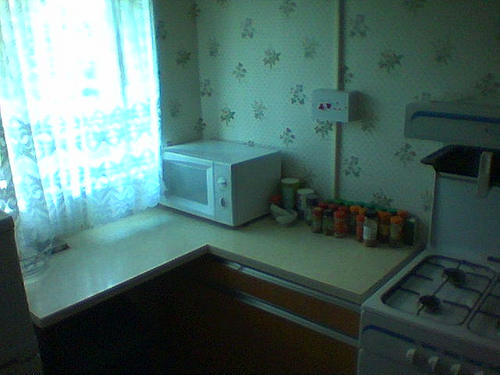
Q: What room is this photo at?
A: It is at the kitchen.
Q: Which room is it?
A: It is a kitchen.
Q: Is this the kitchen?
A: Yes, it is the kitchen.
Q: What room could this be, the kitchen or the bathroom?
A: It is the kitchen.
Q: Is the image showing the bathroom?
A: No, the picture is showing the kitchen.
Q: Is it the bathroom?
A: No, it is the kitchen.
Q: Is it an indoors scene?
A: Yes, it is indoors.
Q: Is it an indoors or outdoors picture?
A: It is indoors.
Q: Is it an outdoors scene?
A: No, it is indoors.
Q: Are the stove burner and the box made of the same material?
A: Yes, both the stove burner and the box are made of metal.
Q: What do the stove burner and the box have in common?
A: The material, both the stove burner and the box are metallic.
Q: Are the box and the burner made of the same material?
A: Yes, both the box and the burner are made of metal.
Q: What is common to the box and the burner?
A: The material, both the box and the burner are metallic.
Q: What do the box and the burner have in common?
A: The material, both the box and the burner are metallic.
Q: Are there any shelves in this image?
A: No, there are no shelves.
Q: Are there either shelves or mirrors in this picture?
A: No, there are no shelves or mirrors.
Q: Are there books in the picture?
A: No, there are no books.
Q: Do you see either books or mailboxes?
A: No, there are no books or mailboxes.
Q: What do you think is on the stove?
A: The stove burner is on the stove.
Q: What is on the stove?
A: The stove burner is on the stove.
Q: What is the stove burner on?
A: The stove burner is on the stove.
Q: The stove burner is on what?
A: The stove burner is on the stove.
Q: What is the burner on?
A: The stove burner is on the stove.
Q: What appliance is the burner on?
A: The burner is on the stove.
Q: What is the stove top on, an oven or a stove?
A: The stove top is on a stove.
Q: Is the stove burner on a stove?
A: Yes, the stove burner is on a stove.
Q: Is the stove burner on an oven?
A: No, the stove burner is on a stove.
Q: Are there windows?
A: Yes, there is a window.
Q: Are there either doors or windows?
A: Yes, there is a window.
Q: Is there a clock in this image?
A: No, there are no clocks.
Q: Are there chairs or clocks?
A: No, there are no clocks or chairs.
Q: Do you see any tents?
A: No, there are no tents.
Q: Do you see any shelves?
A: No, there are no shelves.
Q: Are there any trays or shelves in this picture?
A: No, there are no shelves or trays.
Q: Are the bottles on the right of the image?
A: Yes, the bottles are on the right of the image.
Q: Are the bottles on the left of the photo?
A: No, the bottles are on the right of the image.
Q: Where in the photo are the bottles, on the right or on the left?
A: The bottles are on the right of the image.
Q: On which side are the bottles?
A: The bottles are on the right of the image.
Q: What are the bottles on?
A: The bottles are on the counter top.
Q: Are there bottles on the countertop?
A: Yes, there are bottles on the countertop.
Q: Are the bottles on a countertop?
A: Yes, the bottles are on a countertop.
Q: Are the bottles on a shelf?
A: No, the bottles are on a countertop.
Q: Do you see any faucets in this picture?
A: No, there are no faucets.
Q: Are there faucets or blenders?
A: No, there are no faucets or blenders.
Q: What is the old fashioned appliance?
A: The appliance is a stove.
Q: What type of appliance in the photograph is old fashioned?
A: The appliance is a stove.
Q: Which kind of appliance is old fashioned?
A: The appliance is a stove.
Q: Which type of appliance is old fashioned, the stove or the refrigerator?
A: The stove is old fashioned.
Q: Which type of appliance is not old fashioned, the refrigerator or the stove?
A: The refrigerator is not old fashioned.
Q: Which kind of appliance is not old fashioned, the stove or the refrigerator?
A: The refrigerator is not old fashioned.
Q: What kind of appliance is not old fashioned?
A: The appliance is a refrigerator.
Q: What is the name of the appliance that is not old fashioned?
A: The appliance is a refrigerator.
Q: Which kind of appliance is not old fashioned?
A: The appliance is a refrigerator.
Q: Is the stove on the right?
A: Yes, the stove is on the right of the image.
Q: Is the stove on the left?
A: No, the stove is on the right of the image.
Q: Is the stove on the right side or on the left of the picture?
A: The stove is on the right of the image.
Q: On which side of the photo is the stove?
A: The stove is on the right of the image.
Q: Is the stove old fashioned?
A: Yes, the stove is old fashioned.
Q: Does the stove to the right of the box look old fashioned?
A: Yes, the stove is old fashioned.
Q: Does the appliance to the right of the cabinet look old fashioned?
A: Yes, the stove is old fashioned.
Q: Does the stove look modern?
A: No, the stove is old fashioned.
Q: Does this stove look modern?
A: No, the stove is old fashioned.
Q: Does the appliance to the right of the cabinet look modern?
A: No, the stove is old fashioned.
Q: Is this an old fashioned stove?
A: Yes, this is an old fashioned stove.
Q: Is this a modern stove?
A: No, this is an old fashioned stove.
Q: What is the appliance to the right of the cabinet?
A: The appliance is a stove.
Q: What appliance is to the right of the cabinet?
A: The appliance is a stove.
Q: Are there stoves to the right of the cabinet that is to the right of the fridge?
A: Yes, there is a stove to the right of the cabinet.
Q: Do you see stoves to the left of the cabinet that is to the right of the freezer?
A: No, the stove is to the right of the cabinet.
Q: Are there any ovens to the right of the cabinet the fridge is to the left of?
A: No, there is a stove to the right of the cabinet.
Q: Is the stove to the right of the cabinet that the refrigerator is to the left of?
A: Yes, the stove is to the right of the cabinet.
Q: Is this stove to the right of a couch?
A: No, the stove is to the right of the cabinet.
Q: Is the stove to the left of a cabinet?
A: No, the stove is to the right of a cabinet.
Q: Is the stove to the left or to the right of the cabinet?
A: The stove is to the right of the cabinet.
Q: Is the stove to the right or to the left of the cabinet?
A: The stove is to the right of the cabinet.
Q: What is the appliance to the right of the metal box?
A: The appliance is a stove.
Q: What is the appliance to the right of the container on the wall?
A: The appliance is a stove.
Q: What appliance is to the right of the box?
A: The appliance is a stove.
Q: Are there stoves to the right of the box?
A: Yes, there is a stove to the right of the box.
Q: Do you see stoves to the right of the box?
A: Yes, there is a stove to the right of the box.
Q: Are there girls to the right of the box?
A: No, there is a stove to the right of the box.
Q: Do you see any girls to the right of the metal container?
A: No, there is a stove to the right of the box.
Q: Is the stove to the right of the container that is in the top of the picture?
A: Yes, the stove is to the right of the box.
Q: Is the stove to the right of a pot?
A: No, the stove is to the right of the box.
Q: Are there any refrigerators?
A: Yes, there is a refrigerator.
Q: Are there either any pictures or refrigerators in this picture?
A: Yes, there is a refrigerator.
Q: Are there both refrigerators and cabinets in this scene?
A: Yes, there are both a refrigerator and a cabinet.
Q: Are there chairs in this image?
A: No, there are no chairs.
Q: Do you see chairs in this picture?
A: No, there are no chairs.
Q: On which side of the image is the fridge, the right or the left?
A: The fridge is on the left of the image.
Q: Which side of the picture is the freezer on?
A: The freezer is on the left of the image.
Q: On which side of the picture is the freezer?
A: The freezer is on the left of the image.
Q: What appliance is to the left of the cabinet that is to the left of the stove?
A: The appliance is a refrigerator.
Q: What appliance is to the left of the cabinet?
A: The appliance is a refrigerator.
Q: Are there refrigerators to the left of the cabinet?
A: Yes, there is a refrigerator to the left of the cabinet.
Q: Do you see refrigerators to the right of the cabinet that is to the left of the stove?
A: No, the refrigerator is to the left of the cabinet.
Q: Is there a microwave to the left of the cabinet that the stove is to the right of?
A: No, there is a refrigerator to the left of the cabinet.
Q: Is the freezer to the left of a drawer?
A: No, the freezer is to the left of a cabinet.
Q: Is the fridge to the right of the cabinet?
A: No, the fridge is to the left of the cabinet.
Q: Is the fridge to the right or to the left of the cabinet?
A: The fridge is to the left of the cabinet.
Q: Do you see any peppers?
A: No, there are no peppers.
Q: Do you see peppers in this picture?
A: No, there are no peppers.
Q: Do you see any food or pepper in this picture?
A: No, there are no peppers or food.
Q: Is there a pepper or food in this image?
A: No, there are no peppers or food.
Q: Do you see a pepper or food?
A: No, there are no peppers or food.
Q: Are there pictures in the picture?
A: No, there are no pictures.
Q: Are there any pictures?
A: No, there are no pictures.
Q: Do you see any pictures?
A: No, there are no pictures.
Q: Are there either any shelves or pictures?
A: No, there are no pictures or shelves.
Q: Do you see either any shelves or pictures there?
A: No, there are no pictures or shelves.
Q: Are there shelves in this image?
A: No, there are no shelves.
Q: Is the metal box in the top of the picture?
A: Yes, the box is in the top of the image.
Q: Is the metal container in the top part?
A: Yes, the box is in the top of the image.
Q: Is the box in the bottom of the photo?
A: No, the box is in the top of the image.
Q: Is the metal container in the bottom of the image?
A: No, the box is in the top of the image.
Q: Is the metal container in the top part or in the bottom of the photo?
A: The box is in the top of the image.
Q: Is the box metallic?
A: Yes, the box is metallic.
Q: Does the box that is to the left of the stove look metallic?
A: Yes, the box is metallic.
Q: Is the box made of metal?
A: Yes, the box is made of metal.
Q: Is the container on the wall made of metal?
A: Yes, the box is made of metal.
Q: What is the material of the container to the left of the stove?
A: The box is made of metal.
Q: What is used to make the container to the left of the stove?
A: The box is made of metal.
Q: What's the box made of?
A: The box is made of metal.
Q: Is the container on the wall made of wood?
A: No, the box is made of metal.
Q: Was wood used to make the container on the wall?
A: No, the box is made of metal.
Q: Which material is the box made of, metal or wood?
A: The box is made of metal.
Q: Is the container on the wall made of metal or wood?
A: The box is made of metal.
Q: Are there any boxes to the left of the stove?
A: Yes, there is a box to the left of the stove.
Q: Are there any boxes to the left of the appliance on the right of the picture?
A: Yes, there is a box to the left of the stove.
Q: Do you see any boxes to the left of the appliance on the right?
A: Yes, there is a box to the left of the stove.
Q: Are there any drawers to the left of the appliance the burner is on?
A: No, there is a box to the left of the stove.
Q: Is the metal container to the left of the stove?
A: Yes, the box is to the left of the stove.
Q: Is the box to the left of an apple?
A: No, the box is to the left of the stove.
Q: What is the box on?
A: The box is on the wall.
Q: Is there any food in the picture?
A: No, there is no food.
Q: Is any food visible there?
A: No, there is no food.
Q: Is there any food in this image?
A: No, there is no food.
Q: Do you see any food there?
A: No, there is no food.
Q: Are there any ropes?
A: No, there are no ropes.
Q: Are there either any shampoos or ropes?
A: No, there are no ropes or shampoos.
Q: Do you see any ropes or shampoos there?
A: No, there are no ropes or shampoos.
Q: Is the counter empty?
A: Yes, the counter is empty.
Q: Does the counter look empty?
A: Yes, the counter is empty.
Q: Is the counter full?
A: No, the counter is empty.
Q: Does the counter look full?
A: No, the counter is empty.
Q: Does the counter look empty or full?
A: The counter is empty.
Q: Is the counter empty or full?
A: The counter is empty.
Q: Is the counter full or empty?
A: The counter is empty.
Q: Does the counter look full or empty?
A: The counter is empty.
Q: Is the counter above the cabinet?
A: Yes, the counter is above the cabinet.